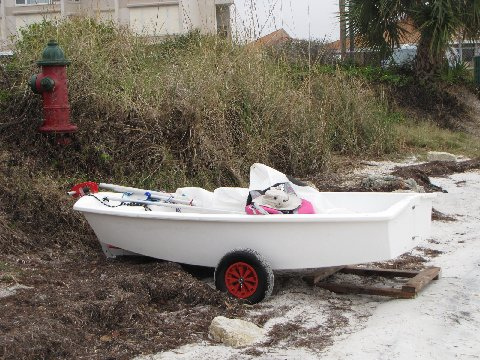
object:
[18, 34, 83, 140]
hydrant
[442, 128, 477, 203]
shore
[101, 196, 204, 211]
poles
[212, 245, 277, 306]
tire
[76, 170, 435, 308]
boat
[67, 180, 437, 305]
dingy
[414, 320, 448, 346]
snow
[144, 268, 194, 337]
ground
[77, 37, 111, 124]
grass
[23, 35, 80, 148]
fire hydrant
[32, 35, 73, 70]
top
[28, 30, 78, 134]
hydrant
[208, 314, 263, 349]
rock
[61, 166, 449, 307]
dingy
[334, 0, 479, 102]
tree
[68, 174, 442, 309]
trailer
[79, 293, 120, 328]
dirt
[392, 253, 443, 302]
wood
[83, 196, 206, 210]
pole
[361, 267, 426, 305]
frame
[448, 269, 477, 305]
ground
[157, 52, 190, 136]
grass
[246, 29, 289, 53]
roof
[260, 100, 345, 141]
seaweed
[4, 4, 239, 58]
building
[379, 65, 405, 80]
plants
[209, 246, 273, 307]
wheels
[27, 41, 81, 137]
hydrant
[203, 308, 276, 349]
boulder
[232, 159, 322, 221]
item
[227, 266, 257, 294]
rim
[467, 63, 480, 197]
slope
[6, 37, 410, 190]
hill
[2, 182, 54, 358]
beach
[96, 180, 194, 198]
pole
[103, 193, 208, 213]
pole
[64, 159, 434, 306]
boat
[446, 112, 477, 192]
bank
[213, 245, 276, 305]
wheel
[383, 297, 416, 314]
snow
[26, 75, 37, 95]
opening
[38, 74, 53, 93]
opening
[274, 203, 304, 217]
stuff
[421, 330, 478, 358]
ground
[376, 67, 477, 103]
bottom